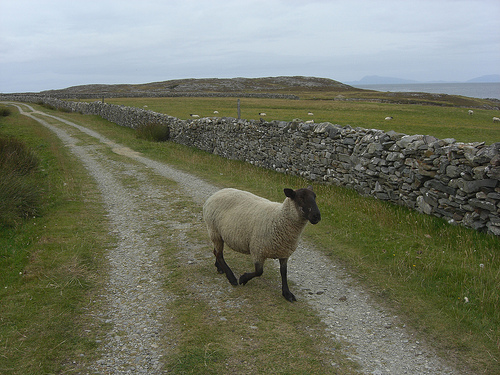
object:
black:
[282, 270, 291, 294]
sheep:
[202, 187, 321, 304]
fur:
[225, 197, 265, 226]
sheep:
[384, 115, 397, 120]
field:
[324, 99, 395, 120]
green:
[350, 231, 384, 256]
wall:
[0, 91, 500, 235]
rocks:
[474, 190, 487, 200]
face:
[294, 188, 321, 225]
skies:
[2, 0, 500, 77]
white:
[267, 220, 294, 246]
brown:
[304, 190, 311, 202]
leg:
[280, 269, 296, 302]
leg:
[237, 271, 261, 285]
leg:
[220, 255, 239, 287]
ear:
[283, 186, 295, 198]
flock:
[211, 106, 320, 125]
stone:
[280, 134, 328, 163]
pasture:
[59, 89, 500, 145]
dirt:
[317, 289, 361, 313]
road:
[0, 98, 499, 373]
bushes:
[1, 135, 42, 230]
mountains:
[354, 72, 495, 105]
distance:
[345, 60, 499, 99]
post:
[235, 98, 242, 118]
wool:
[213, 192, 235, 224]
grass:
[0, 102, 96, 373]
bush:
[134, 120, 168, 139]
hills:
[39, 76, 377, 95]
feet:
[228, 275, 249, 287]